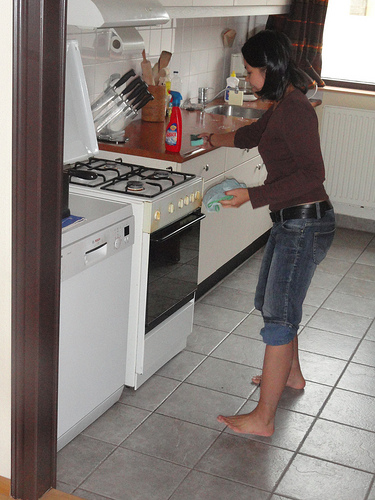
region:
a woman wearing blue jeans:
[196, 29, 339, 438]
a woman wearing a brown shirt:
[202, 30, 337, 438]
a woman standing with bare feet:
[200, 30, 338, 438]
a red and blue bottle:
[162, 89, 185, 155]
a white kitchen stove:
[66, 156, 206, 392]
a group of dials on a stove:
[151, 188, 202, 223]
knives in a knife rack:
[86, 67, 156, 147]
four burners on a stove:
[62, 155, 197, 200]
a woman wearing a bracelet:
[196, 30, 339, 439]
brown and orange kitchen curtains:
[260, 0, 328, 89]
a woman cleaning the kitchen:
[218, 50, 318, 442]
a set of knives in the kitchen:
[96, 66, 151, 145]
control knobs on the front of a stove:
[151, 185, 209, 226]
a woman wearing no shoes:
[213, 27, 316, 449]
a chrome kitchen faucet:
[194, 82, 241, 108]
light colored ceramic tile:
[64, 440, 372, 491]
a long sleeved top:
[230, 94, 328, 212]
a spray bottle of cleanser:
[161, 85, 185, 155]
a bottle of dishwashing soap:
[222, 71, 241, 102]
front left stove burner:
[120, 173, 148, 194]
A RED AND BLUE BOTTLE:
[162, 85, 187, 157]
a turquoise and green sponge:
[187, 129, 207, 150]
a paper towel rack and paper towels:
[104, 23, 150, 61]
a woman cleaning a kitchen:
[184, 22, 340, 451]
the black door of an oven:
[134, 203, 207, 335]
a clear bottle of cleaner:
[222, 67, 241, 108]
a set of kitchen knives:
[87, 67, 158, 150]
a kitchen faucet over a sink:
[180, 81, 244, 114]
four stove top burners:
[63, 151, 201, 206]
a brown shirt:
[228, 87, 336, 220]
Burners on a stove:
[64, 153, 193, 203]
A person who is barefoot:
[214, 356, 312, 464]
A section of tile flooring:
[109, 422, 202, 491]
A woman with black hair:
[231, 23, 317, 102]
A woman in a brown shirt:
[206, 35, 343, 211]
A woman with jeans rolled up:
[213, 20, 339, 436]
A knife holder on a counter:
[85, 65, 160, 144]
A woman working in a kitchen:
[72, 22, 371, 400]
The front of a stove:
[138, 178, 205, 379]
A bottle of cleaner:
[157, 80, 193, 161]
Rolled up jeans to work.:
[242, 29, 321, 342]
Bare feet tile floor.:
[206, 307, 314, 454]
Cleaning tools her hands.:
[186, 113, 249, 217]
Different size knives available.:
[89, 68, 143, 140]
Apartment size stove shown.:
[103, 156, 201, 338]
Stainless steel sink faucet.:
[197, 81, 254, 120]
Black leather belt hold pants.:
[268, 193, 349, 291]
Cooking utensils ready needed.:
[140, 45, 172, 124]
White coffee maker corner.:
[228, 49, 258, 104]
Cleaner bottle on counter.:
[160, 83, 184, 162]